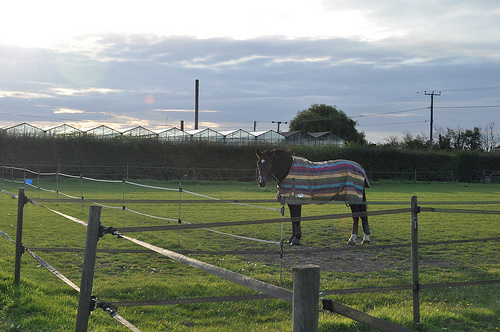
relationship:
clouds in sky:
[71, 25, 428, 95] [2, 4, 499, 146]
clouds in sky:
[71, 25, 428, 95] [0, 0, 496, 129]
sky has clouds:
[0, 0, 496, 129] [71, 25, 428, 95]